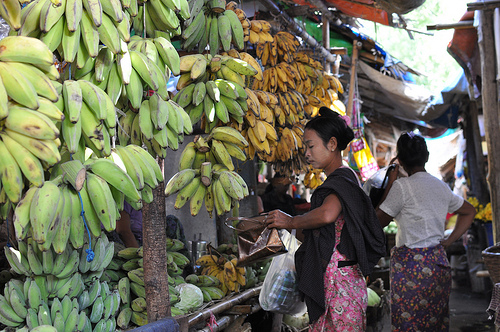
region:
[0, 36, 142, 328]
green bananas and plantains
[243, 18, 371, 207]
ripe yellow bananas on wall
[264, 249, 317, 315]
clear plastic bag with plaid inside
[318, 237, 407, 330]
pink under garmet of woman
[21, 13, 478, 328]
southeast Asia market scene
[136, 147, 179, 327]
trunk of banana tree on left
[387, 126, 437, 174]
black hair of shopper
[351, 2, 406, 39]
orange canvas roof of market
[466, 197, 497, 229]
yellow assorted fruit in background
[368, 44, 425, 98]
blue tarp on market roof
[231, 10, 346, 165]
yellow bananas hanging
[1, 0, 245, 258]
green bananas hanging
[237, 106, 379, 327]
woman in a pink dress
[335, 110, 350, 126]
a pink clip in hair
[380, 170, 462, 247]
a solid white shirt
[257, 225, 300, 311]
a filled white plastic bag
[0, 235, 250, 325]
bananas laying on a table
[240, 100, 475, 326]
two women shopping in a market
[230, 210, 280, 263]
a gold colored bag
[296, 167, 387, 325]
blanket draped over shoulder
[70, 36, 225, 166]
the banana are green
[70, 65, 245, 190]
the banana are yellow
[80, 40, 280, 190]
the banana are hanging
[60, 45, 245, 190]
the banana are delicious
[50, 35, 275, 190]
the banana is healthy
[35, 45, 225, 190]
the banana is yummy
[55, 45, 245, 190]
the banana in the market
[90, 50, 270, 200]
the lady is buying banana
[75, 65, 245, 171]
the banana are for sale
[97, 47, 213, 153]
the banana for sale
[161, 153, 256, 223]
hanging group of unripened bananas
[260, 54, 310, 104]
hanging yellow ripe bananas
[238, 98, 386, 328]
a woman shopping in a pink dress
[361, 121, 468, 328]
a woman wearing a white blouse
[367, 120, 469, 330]
a woman in a patterned skirt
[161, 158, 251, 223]
a large group of thick bananas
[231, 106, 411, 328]
a woman carrying a plastic bag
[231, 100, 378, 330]
a woman with a white translucent bag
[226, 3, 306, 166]
bunches of yellow bananas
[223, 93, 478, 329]
two women in a marketplace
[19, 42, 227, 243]
rack of green bananas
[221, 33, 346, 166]
rack of yellow bananas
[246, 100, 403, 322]
woman in a black shall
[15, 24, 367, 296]
large rack of bananas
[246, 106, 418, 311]
asian woman shopping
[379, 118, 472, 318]
woman in a white blouse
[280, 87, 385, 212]
woman with dark hair put up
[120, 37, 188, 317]
thick wooden post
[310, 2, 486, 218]
awnings over a pathway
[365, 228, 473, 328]
colorfully designed skirt